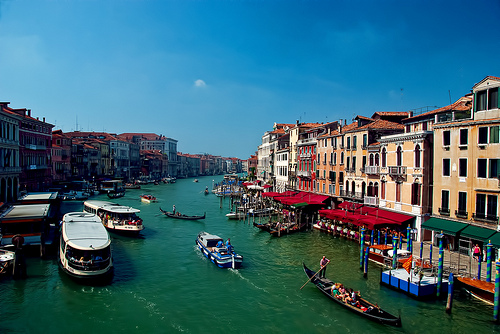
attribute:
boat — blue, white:
[380, 262, 442, 301]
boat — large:
[56, 202, 112, 293]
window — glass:
[439, 130, 452, 147]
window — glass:
[457, 123, 470, 149]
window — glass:
[469, 130, 485, 147]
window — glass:
[478, 130, 485, 144]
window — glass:
[440, 155, 452, 177]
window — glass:
[458, 155, 470, 177]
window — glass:
[472, 160, 484, 180]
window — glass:
[437, 189, 452, 214]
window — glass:
[477, 132, 485, 138]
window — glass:
[472, 86, 483, 108]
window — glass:
[431, 127, 476, 217]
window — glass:
[463, 124, 483, 142]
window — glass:
[475, 123, 484, 136]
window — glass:
[474, 158, 481, 171]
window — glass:
[478, 154, 484, 179]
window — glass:
[436, 151, 452, 177]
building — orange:
[238, 74, 484, 275]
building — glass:
[415, 50, 484, 236]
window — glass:
[469, 82, 484, 124]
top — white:
[61, 201, 112, 255]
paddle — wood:
[300, 259, 330, 292]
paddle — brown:
[288, 255, 332, 292]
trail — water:
[213, 260, 278, 299]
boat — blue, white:
[294, 262, 403, 322]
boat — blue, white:
[298, 258, 405, 328]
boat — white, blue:
[46, 203, 129, 292]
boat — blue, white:
[153, 201, 273, 283]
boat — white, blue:
[182, 220, 277, 283]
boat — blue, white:
[52, 196, 152, 278]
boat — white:
[67, 188, 149, 227]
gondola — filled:
[277, 250, 415, 331]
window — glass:
[457, 158, 467, 177]